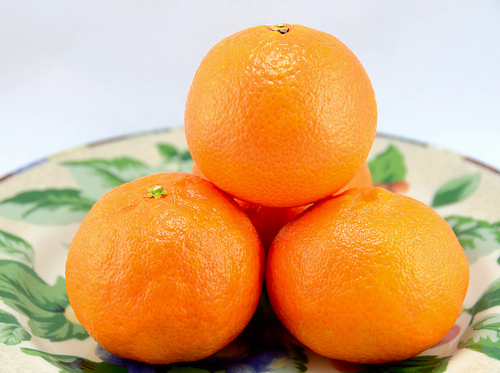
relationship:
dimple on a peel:
[267, 76, 274, 84] [218, 39, 352, 189]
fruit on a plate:
[184, 22, 380, 208] [1, 126, 498, 372]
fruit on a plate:
[65, 172, 266, 365] [1, 126, 498, 372]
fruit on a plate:
[267, 183, 471, 363] [1, 126, 498, 372]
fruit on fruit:
[184, 22, 380, 208] [65, 172, 266, 365]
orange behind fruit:
[191, 162, 373, 254] [65, 172, 266, 365]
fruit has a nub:
[184, 22, 380, 208] [270, 22, 290, 34]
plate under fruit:
[1, 126, 498, 372] [65, 172, 266, 365]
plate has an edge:
[1, 126, 498, 372] [3, 126, 500, 182]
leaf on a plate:
[370, 143, 406, 188] [1, 126, 498, 372]